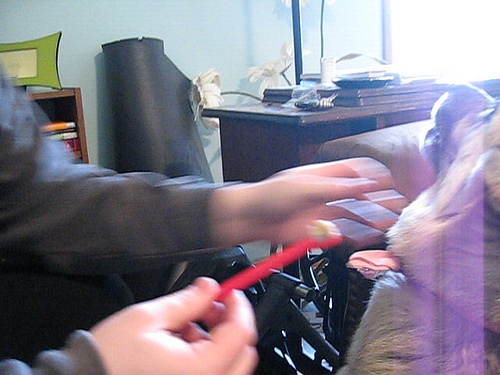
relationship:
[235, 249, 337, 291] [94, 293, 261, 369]
object in hand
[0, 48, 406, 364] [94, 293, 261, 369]
man has hand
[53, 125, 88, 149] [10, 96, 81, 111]
books on shelf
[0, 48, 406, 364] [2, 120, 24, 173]
man has hair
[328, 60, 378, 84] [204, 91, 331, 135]
dish on desk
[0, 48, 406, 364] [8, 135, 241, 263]
man has arm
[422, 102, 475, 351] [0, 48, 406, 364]
dog next to man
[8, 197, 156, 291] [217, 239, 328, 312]
man holding straw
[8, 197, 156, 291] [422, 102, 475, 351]
man reaching for dog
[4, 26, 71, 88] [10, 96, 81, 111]
picture frame on top of shelf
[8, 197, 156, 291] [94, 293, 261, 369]
man has hand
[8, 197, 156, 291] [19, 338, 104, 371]
man wearing shirt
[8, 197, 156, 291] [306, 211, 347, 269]
man holding toothbrush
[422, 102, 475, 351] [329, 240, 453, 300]
dog wearing bandana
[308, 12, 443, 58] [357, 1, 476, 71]
light in window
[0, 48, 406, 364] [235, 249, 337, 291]
man holding object